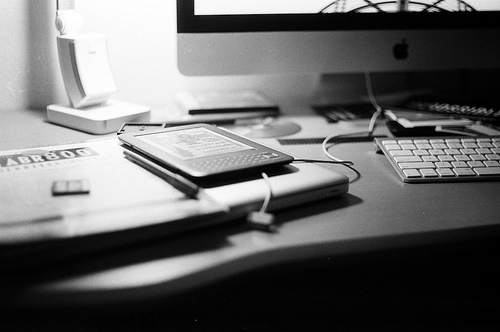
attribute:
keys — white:
[402, 166, 420, 176]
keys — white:
[455, 166, 476, 176]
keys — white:
[440, 166, 456, 176]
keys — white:
[474, 162, 498, 174]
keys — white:
[383, 138, 400, 147]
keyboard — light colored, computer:
[374, 124, 499, 184]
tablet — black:
[114, 121, 296, 181]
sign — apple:
[357, 17, 435, 77]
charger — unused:
[237, 198, 283, 226]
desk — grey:
[353, 173, 398, 235]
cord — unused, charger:
[260, 104, 383, 214]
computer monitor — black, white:
[177, 5, 495, 112]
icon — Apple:
[360, 29, 412, 67]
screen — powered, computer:
[196, 0, 481, 15]